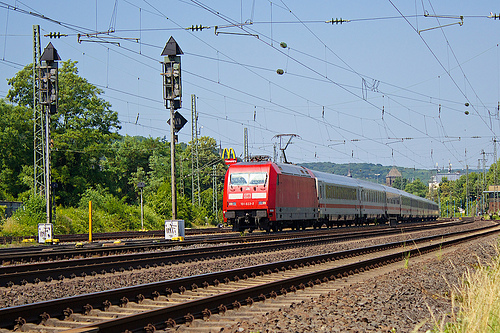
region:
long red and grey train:
[224, 161, 443, 224]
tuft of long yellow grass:
[416, 254, 498, 330]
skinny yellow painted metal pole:
[87, 195, 97, 240]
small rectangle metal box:
[161, 216, 181, 238]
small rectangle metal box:
[36, 217, 53, 237]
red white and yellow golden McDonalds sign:
[218, 142, 235, 167]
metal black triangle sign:
[162, 33, 182, 53]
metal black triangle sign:
[38, 40, 61, 61]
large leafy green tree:
[5, 60, 120, 205]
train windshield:
[227, 172, 268, 184]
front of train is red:
[216, 146, 316, 208]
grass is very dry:
[453, 257, 499, 327]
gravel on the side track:
[411, 260, 426, 330]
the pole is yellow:
[90, 189, 93, 246]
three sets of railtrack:
[93, 237, 242, 332]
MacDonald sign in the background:
[216, 129, 241, 161]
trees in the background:
[351, 158, 395, 175]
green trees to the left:
[97, 149, 161, 203]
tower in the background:
[386, 162, 405, 183]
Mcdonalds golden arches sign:
[218, 145, 239, 163]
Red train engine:
[221, 160, 316, 227]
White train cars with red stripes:
[315, 175, 400, 217]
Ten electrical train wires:
[126, 13, 356, 34]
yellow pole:
[85, 195, 91, 240]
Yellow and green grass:
[445, 260, 495, 330]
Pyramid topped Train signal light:
[156, 31, 188, 111]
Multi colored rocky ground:
[316, 286, 422, 326]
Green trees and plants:
[50, 125, 165, 200]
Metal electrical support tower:
[186, 85, 199, 220]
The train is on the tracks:
[209, 170, 445, 328]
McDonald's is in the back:
[206, 139, 243, 167]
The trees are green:
[8, 90, 143, 185]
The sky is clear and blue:
[256, 61, 430, 178]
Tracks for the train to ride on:
[153, 241, 265, 329]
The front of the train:
[217, 154, 302, 248]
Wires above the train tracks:
[172, 34, 395, 167]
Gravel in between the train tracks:
[115, 263, 242, 293]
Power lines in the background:
[234, 101, 319, 163]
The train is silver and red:
[226, 180, 416, 251]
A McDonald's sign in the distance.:
[215, 135, 236, 161]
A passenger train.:
[216, 150, 441, 225]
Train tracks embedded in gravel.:
[145, 235, 305, 311]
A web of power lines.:
[240, 10, 465, 145]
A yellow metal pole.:
[75, 190, 100, 241]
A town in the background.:
[375, 161, 480, 191]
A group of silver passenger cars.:
[307, 156, 447, 226]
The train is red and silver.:
[215, 147, 462, 227]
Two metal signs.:
[30, 36, 200, 246]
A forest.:
[66, 92, 156, 197]